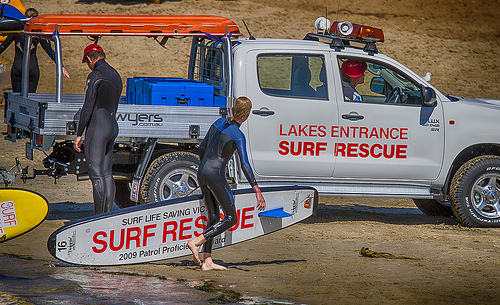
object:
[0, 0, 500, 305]
beach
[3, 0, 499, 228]
vehicle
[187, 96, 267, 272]
person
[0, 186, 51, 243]
surfboard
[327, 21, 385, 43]
light